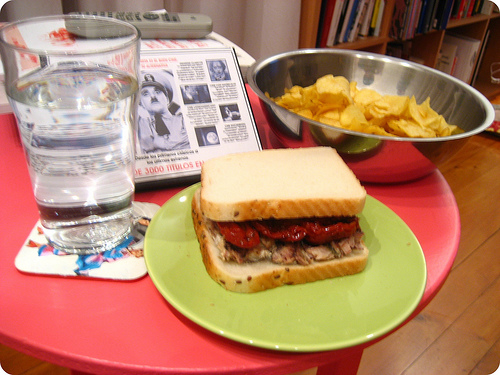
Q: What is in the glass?
A: Water.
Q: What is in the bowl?
A: Potato chips.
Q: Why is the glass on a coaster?
A: Keep table dry.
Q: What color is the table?
A: Red.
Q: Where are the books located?
A: Bookshelves.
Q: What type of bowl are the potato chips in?
A: Stainless steel.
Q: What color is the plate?
A: Green.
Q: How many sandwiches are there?
A: 1.